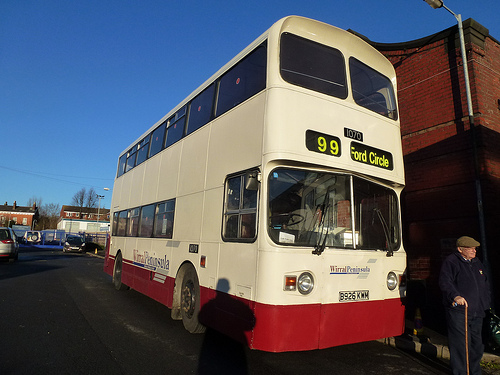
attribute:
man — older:
[435, 233, 497, 373]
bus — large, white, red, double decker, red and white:
[101, 24, 412, 352]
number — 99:
[309, 129, 339, 159]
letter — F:
[348, 143, 355, 160]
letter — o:
[353, 149, 357, 159]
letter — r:
[357, 150, 362, 160]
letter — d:
[363, 152, 367, 163]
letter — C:
[368, 150, 376, 165]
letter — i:
[372, 155, 375, 166]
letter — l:
[380, 154, 385, 169]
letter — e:
[383, 156, 391, 166]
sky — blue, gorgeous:
[2, 0, 499, 219]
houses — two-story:
[1, 193, 112, 266]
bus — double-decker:
[97, 34, 446, 356]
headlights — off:
[266, 241, 416, 296]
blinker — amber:
[282, 267, 304, 310]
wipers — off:
[314, 179, 417, 258]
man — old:
[424, 240, 488, 372]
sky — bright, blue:
[12, 20, 159, 85]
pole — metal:
[427, 30, 499, 296]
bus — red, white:
[94, 30, 398, 334]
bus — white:
[83, 37, 414, 369]